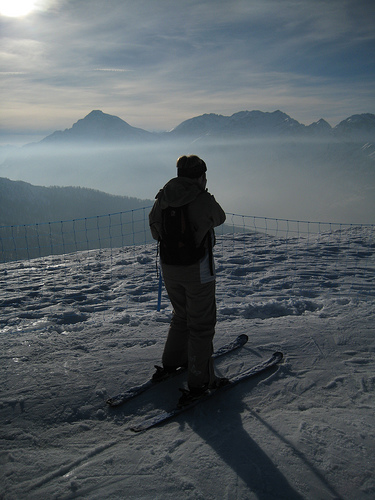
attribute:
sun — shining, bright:
[3, 4, 60, 66]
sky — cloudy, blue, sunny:
[3, 1, 373, 129]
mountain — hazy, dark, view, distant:
[49, 111, 144, 134]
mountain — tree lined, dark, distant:
[169, 108, 332, 131]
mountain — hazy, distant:
[338, 111, 371, 127]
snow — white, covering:
[2, 227, 372, 499]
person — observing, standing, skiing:
[147, 155, 226, 394]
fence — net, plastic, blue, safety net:
[1, 214, 374, 273]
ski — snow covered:
[133, 347, 283, 431]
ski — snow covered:
[106, 331, 253, 410]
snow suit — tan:
[147, 181, 226, 387]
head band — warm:
[175, 162, 205, 176]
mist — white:
[3, 134, 370, 227]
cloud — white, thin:
[2, 52, 125, 75]